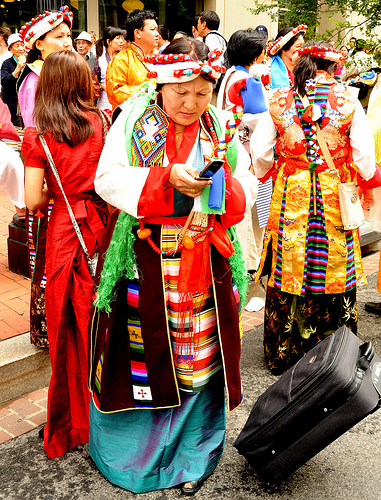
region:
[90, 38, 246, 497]
woman in colorful traditional garb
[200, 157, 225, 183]
flip style cell phone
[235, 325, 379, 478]
suitcase with handles and wheels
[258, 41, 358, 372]
back of another woman dressed in very colorful traditional garb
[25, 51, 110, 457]
back of red haired woman in solid red long dress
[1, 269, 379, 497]
street with many people dressed for an event or show standing on it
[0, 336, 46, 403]
high cement curb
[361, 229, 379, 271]
storm drain in cement curb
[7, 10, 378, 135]
crowd mostly in native garb in background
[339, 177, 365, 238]
white shoulder bag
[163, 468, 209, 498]
tip of black shoes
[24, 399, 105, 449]
hem of red silk dress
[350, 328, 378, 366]
handle of black suitcase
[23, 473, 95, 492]
white spots on ground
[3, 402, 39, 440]
red tiles on ground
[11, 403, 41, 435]
white stripes in red tiles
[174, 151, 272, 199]
cell phone in woman's hand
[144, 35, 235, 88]
decorative head band on woman's head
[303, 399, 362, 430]
silver studs at bottom of suitcase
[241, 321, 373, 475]
large black suit case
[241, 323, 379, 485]
a black suitcase on wheels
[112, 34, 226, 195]
a older woman looking at her phone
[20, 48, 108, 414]
a woman in a long red dress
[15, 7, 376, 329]
a group of colorful people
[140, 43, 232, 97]
red and blue balls on a white bandana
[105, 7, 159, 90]
a man in yellow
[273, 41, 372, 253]
a woman wearing a white purse over her shoulder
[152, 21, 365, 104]
three woman wearing the same head piece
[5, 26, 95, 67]
two men that could be twins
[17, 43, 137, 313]
a woman with her back to the camera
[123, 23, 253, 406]
woman wearing tribal clothing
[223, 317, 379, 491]
black suitcase on ground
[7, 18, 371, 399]
many people gathered together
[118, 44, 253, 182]
woman looking at cellphone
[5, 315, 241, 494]
woman standing on street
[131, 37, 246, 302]
woman has head dress on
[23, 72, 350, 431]
three women in street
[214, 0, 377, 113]
only one tree in background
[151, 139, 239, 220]
using a black cell phone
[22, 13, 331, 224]
more women than men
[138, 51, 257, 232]
a woman on a cell phone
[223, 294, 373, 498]
a black suitcase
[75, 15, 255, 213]
a woman on a black cell phone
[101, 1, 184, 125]
a man wearing a yellow shirt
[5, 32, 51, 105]
a man wearing a hat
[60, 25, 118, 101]
a man wearing glasses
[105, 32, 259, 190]
a woman wearing a headband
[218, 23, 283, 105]
a person with black hair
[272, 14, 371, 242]
a woman wearing a bag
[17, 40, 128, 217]
a woman with brown hair